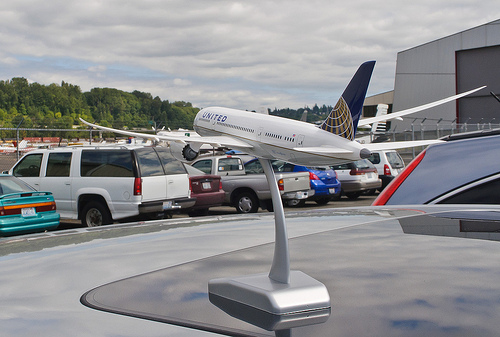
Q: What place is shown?
A: It is a parking lot.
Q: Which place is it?
A: It is a parking lot.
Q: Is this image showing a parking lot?
A: Yes, it is showing a parking lot.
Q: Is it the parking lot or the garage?
A: It is the parking lot.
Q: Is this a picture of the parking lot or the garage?
A: It is showing the parking lot.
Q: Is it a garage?
A: No, it is a parking lot.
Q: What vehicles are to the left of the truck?
A: The vehicles are cars.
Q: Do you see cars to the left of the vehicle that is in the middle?
A: Yes, there are cars to the left of the truck.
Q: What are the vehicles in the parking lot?
A: The vehicles are cars.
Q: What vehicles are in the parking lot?
A: The vehicles are cars.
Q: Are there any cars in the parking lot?
A: Yes, there are cars in the parking lot.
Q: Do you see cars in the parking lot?
A: Yes, there are cars in the parking lot.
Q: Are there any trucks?
A: Yes, there is a truck.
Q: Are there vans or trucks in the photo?
A: Yes, there is a truck.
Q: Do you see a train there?
A: No, there are no trains.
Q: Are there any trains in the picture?
A: No, there are no trains.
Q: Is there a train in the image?
A: No, there are no trains.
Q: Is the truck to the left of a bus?
A: No, the truck is to the left of the car.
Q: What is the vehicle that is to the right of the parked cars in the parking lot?
A: The vehicle is a truck.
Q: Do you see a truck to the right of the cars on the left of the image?
A: Yes, there is a truck to the right of the cars.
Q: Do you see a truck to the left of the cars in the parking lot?
A: No, the truck is to the right of the cars.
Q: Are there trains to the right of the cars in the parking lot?
A: No, there is a truck to the right of the cars.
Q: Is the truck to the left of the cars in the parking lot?
A: No, the truck is to the right of the cars.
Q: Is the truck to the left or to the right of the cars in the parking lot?
A: The truck is to the right of the cars.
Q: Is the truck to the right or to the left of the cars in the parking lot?
A: The truck is to the right of the cars.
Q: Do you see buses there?
A: No, there are no buses.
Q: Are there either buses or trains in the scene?
A: No, there are no buses or trains.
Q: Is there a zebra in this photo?
A: No, there are no zebras.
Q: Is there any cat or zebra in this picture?
A: No, there are no zebras or cats.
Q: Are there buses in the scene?
A: No, there are no buses.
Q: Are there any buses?
A: No, there are no buses.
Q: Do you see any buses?
A: No, there are no buses.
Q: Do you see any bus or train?
A: No, there are no buses or trains.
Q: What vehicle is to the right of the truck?
A: The vehicle is a car.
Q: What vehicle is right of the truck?
A: The vehicle is a car.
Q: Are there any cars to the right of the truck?
A: Yes, there is a car to the right of the truck.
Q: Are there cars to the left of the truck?
A: No, the car is to the right of the truck.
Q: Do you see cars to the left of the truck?
A: No, the car is to the right of the truck.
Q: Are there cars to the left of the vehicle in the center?
A: No, the car is to the right of the truck.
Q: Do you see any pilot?
A: No, there are no pilots.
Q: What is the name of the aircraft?
A: The aircraft is a jet.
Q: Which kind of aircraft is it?
A: The aircraft is a jet.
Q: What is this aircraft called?
A: This is a jet.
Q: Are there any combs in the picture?
A: No, there are no combs.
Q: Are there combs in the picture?
A: No, there are no combs.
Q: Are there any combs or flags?
A: No, there are no combs or flags.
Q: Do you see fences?
A: Yes, there is a fence.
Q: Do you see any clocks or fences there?
A: Yes, there is a fence.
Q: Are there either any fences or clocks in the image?
A: Yes, there is a fence.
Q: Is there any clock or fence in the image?
A: Yes, there is a fence.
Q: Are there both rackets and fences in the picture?
A: No, there is a fence but no rackets.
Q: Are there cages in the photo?
A: No, there are no cages.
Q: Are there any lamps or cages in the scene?
A: No, there are no cages or lamps.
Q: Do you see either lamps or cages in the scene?
A: No, there are no cages or lamps.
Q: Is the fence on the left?
A: Yes, the fence is on the left of the image.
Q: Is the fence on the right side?
A: No, the fence is on the left of the image.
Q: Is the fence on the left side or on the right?
A: The fence is on the left of the image.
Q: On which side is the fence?
A: The fence is on the left of the image.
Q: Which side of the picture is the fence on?
A: The fence is on the left of the image.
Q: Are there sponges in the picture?
A: No, there are no sponges.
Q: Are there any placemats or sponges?
A: No, there are no sponges or placemats.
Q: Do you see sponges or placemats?
A: No, there are no sponges or placemats.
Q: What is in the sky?
A: The clouds are in the sky.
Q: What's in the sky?
A: The clouds are in the sky.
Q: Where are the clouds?
A: The clouds are in the sky.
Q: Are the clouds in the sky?
A: Yes, the clouds are in the sky.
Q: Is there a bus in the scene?
A: No, there are no buses.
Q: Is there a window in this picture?
A: Yes, there are windows.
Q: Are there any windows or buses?
A: Yes, there are windows.